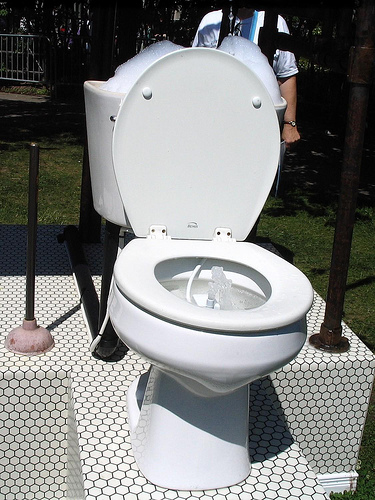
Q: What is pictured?
A: Toilet.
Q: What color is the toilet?
A: White.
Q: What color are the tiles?
A: Black and white.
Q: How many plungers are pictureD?
A: One.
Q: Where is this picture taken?
A: At an exhibit.